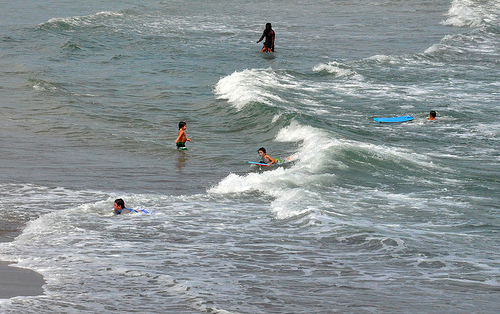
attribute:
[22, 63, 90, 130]
water — blue, white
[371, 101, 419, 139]
board — blue